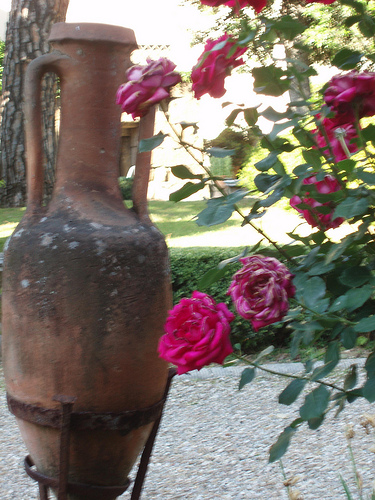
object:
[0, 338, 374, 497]
gravel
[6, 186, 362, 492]
ground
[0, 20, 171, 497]
brown vase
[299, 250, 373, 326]
leaf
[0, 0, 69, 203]
tree bark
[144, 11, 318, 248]
sunlight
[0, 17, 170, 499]
pot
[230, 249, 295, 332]
rose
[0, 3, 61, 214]
tree trunk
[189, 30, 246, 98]
roses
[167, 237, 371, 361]
bush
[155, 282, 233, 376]
flowers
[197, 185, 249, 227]
leaves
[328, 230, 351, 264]
leaves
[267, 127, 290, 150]
leaves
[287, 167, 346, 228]
rose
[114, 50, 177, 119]
rose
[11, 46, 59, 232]
handle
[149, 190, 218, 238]
grass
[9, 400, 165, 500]
base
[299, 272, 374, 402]
shrubbery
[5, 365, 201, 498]
pot holder